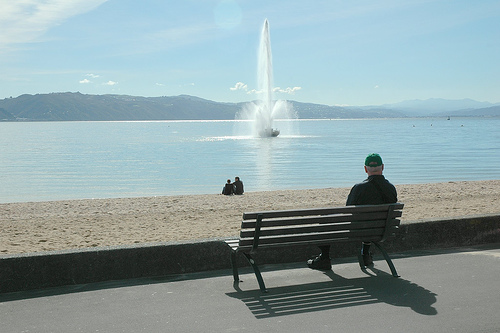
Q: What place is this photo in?
A: It is at the lake.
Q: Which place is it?
A: It is a lake.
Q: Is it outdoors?
A: Yes, it is outdoors.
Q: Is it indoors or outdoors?
A: It is outdoors.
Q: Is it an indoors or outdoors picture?
A: It is outdoors.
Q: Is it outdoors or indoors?
A: It is outdoors.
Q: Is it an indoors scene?
A: No, it is outdoors.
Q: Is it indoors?
A: No, it is outdoors.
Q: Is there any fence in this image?
A: No, there are no fences.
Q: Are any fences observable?
A: No, there are no fences.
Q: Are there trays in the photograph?
A: No, there are no trays.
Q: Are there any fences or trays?
A: No, there are no trays or fences.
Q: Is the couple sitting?
A: Yes, the couple is sitting.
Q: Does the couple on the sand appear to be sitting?
A: Yes, the couple is sitting.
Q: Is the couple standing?
A: No, the couple is sitting.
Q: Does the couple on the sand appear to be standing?
A: No, the couple is sitting.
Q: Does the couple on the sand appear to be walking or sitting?
A: The couple is sitting.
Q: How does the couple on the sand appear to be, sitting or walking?
A: The couple is sitting.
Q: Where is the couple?
A: The couple is on the sand.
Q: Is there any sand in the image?
A: Yes, there is sand.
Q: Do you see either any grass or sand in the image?
A: Yes, there is sand.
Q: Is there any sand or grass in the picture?
A: Yes, there is sand.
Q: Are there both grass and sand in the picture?
A: No, there is sand but no grass.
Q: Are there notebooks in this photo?
A: No, there are no notebooks.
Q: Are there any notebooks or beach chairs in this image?
A: No, there are no notebooks or beach chairs.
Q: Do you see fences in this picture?
A: No, there are no fences.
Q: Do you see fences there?
A: No, there are no fences.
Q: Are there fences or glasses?
A: No, there are no fences or glasses.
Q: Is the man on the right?
A: Yes, the man is on the right of the image.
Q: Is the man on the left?
A: No, the man is on the right of the image.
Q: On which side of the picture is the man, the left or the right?
A: The man is on the right of the image.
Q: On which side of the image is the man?
A: The man is on the right of the image.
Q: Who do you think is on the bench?
A: The man is on the bench.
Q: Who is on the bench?
A: The man is on the bench.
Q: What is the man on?
A: The man is on the bench.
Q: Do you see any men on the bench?
A: Yes, there is a man on the bench.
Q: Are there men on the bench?
A: Yes, there is a man on the bench.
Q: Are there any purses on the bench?
A: No, there is a man on the bench.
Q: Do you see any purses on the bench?
A: No, there is a man on the bench.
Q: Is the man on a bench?
A: Yes, the man is on a bench.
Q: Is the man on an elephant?
A: No, the man is on a bench.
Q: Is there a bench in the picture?
A: Yes, there is a bench.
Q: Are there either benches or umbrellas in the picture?
A: Yes, there is a bench.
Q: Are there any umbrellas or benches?
A: Yes, there is a bench.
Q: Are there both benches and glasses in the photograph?
A: No, there is a bench but no glasses.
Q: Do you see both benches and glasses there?
A: No, there is a bench but no glasses.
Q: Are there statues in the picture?
A: No, there are no statues.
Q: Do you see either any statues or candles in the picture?
A: No, there are no statues or candles.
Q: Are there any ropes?
A: No, there are no ropes.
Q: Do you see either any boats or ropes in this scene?
A: No, there are no ropes or boats.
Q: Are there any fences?
A: No, there are no fences.